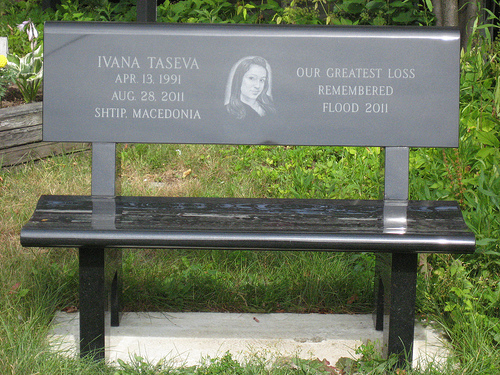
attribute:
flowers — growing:
[1, 19, 43, 107]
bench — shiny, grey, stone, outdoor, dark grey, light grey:
[18, 18, 478, 373]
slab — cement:
[50, 302, 450, 372]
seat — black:
[20, 188, 482, 258]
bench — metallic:
[17, 185, 474, 256]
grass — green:
[178, 254, 366, 304]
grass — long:
[140, 250, 381, 310]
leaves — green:
[475, 122, 495, 204]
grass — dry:
[143, 164, 213, 185]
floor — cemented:
[116, 313, 373, 364]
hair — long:
[227, 53, 285, 125]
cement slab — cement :
[39, 298, 468, 373]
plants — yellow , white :
[0, 11, 47, 105]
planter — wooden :
[2, 83, 107, 168]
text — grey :
[287, 51, 425, 132]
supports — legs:
[71, 243, 434, 371]